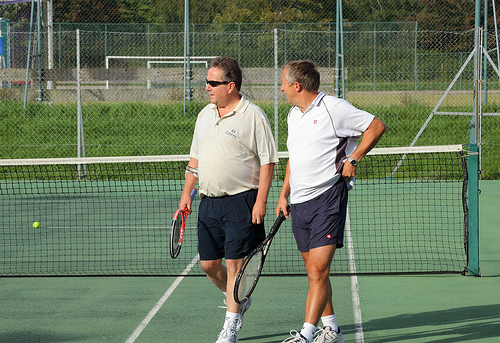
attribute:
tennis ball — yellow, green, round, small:
[33, 221, 40, 228]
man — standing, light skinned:
[179, 58, 281, 342]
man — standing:
[276, 60, 387, 342]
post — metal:
[273, 28, 279, 180]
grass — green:
[0, 81, 499, 182]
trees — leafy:
[0, 1, 499, 69]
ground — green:
[0, 179, 499, 343]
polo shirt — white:
[286, 92, 377, 206]